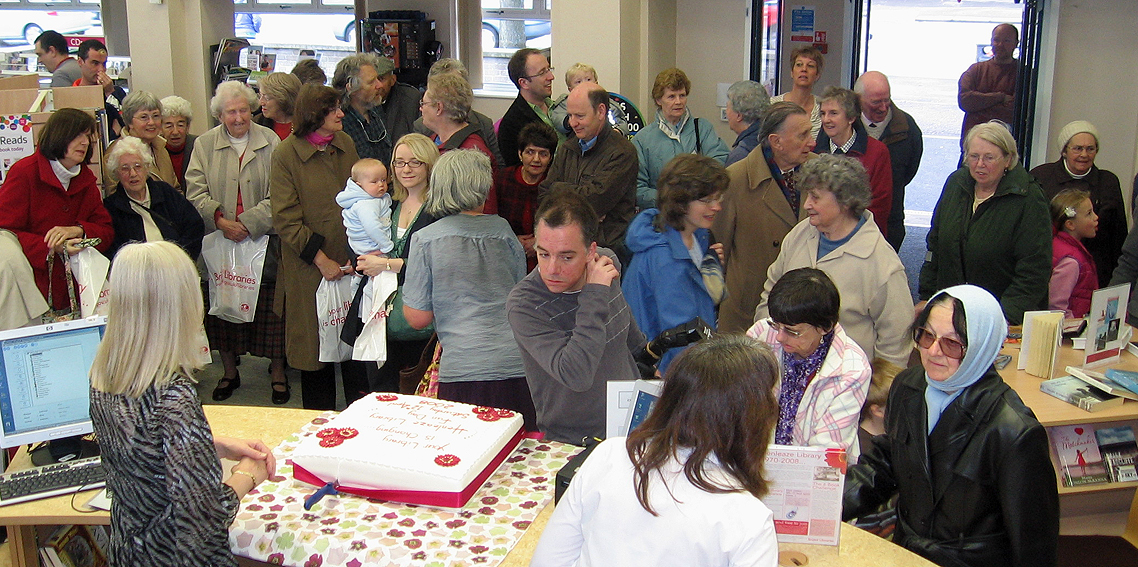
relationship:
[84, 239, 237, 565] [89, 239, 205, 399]
woman has hair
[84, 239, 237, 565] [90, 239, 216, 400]
woman has hair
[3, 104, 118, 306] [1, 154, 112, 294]
woman wearing coat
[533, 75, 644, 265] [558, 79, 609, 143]
man has head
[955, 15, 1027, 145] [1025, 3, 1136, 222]
man leaning against wall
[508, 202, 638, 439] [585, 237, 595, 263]
man touching ear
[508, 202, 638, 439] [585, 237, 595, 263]
man has ear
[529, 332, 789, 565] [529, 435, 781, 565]
woman wearing shirt